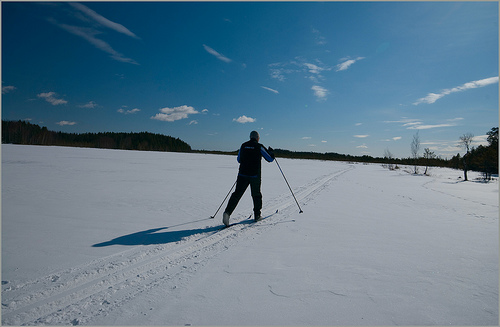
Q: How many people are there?
A: 1.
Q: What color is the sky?
A: Blue.